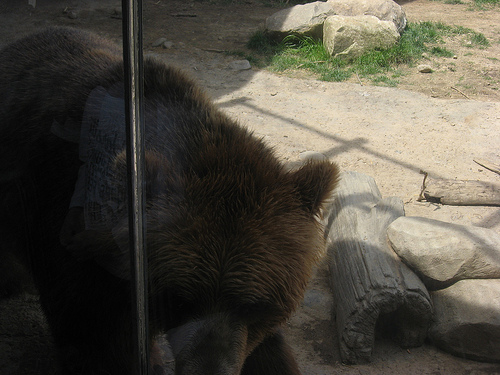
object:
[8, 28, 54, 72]
fur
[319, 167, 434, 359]
log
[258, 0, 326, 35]
stones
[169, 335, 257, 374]
snout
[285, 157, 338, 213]
ears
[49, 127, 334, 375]
head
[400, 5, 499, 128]
ground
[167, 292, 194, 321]
eyes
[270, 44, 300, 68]
grass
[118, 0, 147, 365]
pole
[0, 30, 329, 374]
bear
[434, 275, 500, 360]
rocks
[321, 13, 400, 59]
rocks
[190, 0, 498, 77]
background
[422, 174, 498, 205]
bark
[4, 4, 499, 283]
day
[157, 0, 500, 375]
windows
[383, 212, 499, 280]
rock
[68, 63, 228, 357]
reflection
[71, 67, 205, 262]
boy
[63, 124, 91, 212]
sleeves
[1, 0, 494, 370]
zoo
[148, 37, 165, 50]
rocks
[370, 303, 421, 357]
hole